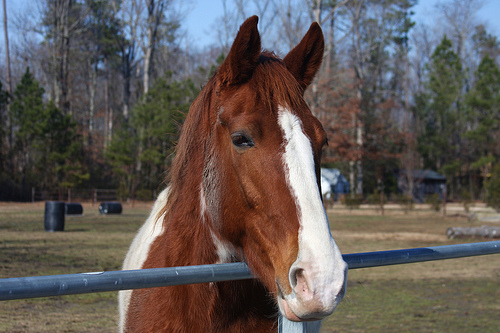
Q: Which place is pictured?
A: It is a forest.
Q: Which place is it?
A: It is a forest.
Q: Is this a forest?
A: Yes, it is a forest.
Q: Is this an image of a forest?
A: Yes, it is showing a forest.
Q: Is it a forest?
A: Yes, it is a forest.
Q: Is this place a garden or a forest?
A: It is a forest.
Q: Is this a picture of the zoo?
A: No, the picture is showing the forest.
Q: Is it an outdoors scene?
A: Yes, it is outdoors.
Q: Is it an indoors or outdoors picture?
A: It is outdoors.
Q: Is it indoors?
A: No, it is outdoors.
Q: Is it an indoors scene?
A: No, it is outdoors.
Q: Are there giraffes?
A: No, there are no giraffes.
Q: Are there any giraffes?
A: No, there are no giraffes.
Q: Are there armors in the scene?
A: No, there are no armors.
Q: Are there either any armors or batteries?
A: No, there are no armors or batteries.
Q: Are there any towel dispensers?
A: No, there are no towel dispensers.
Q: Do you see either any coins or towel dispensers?
A: No, there are no towel dispensers or coins.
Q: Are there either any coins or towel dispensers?
A: No, there are no towel dispensers or coins.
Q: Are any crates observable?
A: No, there are no crates.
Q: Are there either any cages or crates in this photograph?
A: No, there are no crates or cages.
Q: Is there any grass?
A: Yes, there is grass.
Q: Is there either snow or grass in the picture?
A: Yes, there is grass.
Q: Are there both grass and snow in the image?
A: No, there is grass but no snow.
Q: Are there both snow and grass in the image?
A: No, there is grass but no snow.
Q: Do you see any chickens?
A: No, there are no chickens.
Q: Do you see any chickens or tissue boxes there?
A: No, there are no chickens or tissue boxes.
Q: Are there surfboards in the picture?
A: No, there are no surfboards.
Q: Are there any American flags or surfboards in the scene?
A: No, there are no surfboards or American flags.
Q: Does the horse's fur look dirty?
A: Yes, the fur is dirty.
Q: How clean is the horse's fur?
A: The fur is dirty.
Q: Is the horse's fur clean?
A: No, the fur is dirty.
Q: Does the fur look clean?
A: No, the fur is dirty.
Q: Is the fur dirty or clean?
A: The fur is dirty.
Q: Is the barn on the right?
A: Yes, the barn is on the right of the image.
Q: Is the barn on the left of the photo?
A: No, the barn is on the right of the image.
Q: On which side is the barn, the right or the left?
A: The barn is on the right of the image.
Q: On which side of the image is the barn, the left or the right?
A: The barn is on the right of the image.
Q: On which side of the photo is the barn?
A: The barn is on the right of the image.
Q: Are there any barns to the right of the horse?
A: Yes, there is a barn to the right of the horse.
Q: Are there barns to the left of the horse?
A: No, the barn is to the right of the horse.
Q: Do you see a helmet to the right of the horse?
A: No, there is a barn to the right of the horse.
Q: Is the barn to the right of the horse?
A: Yes, the barn is to the right of the horse.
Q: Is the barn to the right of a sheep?
A: No, the barn is to the right of the horse.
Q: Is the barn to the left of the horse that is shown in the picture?
A: No, the barn is to the right of the horse.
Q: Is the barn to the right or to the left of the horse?
A: The barn is to the right of the horse.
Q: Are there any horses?
A: Yes, there is a horse.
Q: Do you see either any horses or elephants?
A: Yes, there is a horse.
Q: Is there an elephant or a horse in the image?
A: Yes, there is a horse.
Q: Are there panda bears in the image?
A: No, there are no panda bears.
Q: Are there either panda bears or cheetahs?
A: No, there are no panda bears or cheetahs.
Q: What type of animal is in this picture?
A: The animal is a horse.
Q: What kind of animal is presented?
A: The animal is a horse.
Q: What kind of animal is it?
A: The animal is a horse.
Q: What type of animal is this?
A: This is a horse.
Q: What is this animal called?
A: This is a horse.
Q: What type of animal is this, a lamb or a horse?
A: This is a horse.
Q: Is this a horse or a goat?
A: This is a horse.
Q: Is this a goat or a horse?
A: This is a horse.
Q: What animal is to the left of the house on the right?
A: The animal is a horse.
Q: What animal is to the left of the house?
A: The animal is a horse.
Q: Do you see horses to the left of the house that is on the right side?
A: Yes, there is a horse to the left of the house.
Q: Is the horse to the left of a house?
A: Yes, the horse is to the left of a house.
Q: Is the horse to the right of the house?
A: No, the horse is to the left of the house.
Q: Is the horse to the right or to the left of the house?
A: The horse is to the left of the house.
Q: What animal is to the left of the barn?
A: The animal is a horse.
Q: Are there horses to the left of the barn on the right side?
A: Yes, there is a horse to the left of the barn.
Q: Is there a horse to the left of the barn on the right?
A: Yes, there is a horse to the left of the barn.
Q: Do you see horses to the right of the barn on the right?
A: No, the horse is to the left of the barn.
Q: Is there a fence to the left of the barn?
A: No, there is a horse to the left of the barn.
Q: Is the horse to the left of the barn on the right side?
A: Yes, the horse is to the left of the barn.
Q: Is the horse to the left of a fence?
A: No, the horse is to the left of the barn.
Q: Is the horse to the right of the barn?
A: No, the horse is to the left of the barn.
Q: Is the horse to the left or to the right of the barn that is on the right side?
A: The horse is to the left of the barn.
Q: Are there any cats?
A: No, there are no cats.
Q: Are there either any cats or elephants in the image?
A: No, there are no cats or elephants.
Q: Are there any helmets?
A: No, there are no helmets.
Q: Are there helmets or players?
A: No, there are no helmets or players.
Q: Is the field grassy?
A: Yes, the field is grassy.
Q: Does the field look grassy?
A: Yes, the field is grassy.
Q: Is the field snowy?
A: No, the field is grassy.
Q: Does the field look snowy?
A: No, the field is grassy.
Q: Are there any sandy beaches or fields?
A: No, there is a field but it is grassy.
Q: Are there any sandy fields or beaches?
A: No, there is a field but it is grassy.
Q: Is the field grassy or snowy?
A: The field is grassy.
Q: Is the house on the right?
A: Yes, the house is on the right of the image.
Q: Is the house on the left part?
A: No, the house is on the right of the image.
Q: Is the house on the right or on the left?
A: The house is on the right of the image.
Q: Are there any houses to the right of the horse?
A: Yes, there is a house to the right of the horse.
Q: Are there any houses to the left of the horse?
A: No, the house is to the right of the horse.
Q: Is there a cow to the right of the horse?
A: No, there is a house to the right of the horse.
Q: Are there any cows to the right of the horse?
A: No, there is a house to the right of the horse.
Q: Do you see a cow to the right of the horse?
A: No, there is a house to the right of the horse.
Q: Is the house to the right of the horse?
A: Yes, the house is to the right of the horse.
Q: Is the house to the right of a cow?
A: No, the house is to the right of the horse.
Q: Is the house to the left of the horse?
A: No, the house is to the right of the horse.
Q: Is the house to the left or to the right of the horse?
A: The house is to the right of the horse.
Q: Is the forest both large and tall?
A: Yes, the forest is large and tall.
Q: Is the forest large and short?
A: No, the forest is large but tall.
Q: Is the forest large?
A: Yes, the forest is large.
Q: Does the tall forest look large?
A: Yes, the forest is large.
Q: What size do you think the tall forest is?
A: The forest is large.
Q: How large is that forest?
A: The forest is large.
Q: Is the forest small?
A: No, the forest is large.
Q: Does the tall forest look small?
A: No, the forest is large.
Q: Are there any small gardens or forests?
A: No, there is a forest but it is large.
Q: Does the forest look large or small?
A: The forest is large.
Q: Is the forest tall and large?
A: Yes, the forest is tall and large.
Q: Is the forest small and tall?
A: No, the forest is tall but large.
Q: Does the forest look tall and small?
A: No, the forest is tall but large.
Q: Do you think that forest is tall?
A: Yes, the forest is tall.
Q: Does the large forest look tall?
A: Yes, the forest is tall.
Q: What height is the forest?
A: The forest is tall.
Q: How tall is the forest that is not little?
A: The forest is tall.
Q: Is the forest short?
A: No, the forest is tall.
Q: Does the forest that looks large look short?
A: No, the forest is tall.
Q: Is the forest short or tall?
A: The forest is tall.